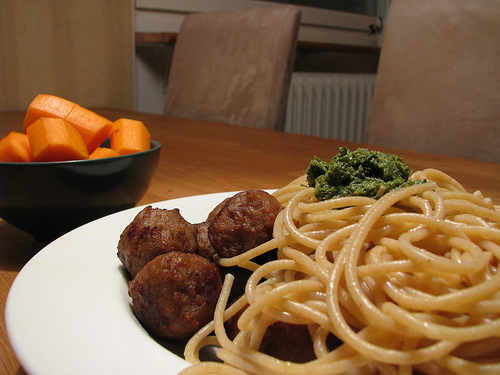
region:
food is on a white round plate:
[1, 146, 496, 371]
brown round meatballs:
[125, 248, 220, 335]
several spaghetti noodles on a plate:
[299, 201, 489, 363]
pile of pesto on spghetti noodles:
[306, 144, 411, 196]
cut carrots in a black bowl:
[1, 93, 160, 242]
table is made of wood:
[6, 102, 499, 198]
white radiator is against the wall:
[290, 70, 372, 132]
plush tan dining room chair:
[164, 6, 302, 128]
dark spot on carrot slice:
[111, 124, 120, 136]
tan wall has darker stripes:
[4, 7, 134, 91]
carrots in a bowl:
[0, 99, 180, 239]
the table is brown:
[143, 100, 227, 205]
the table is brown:
[151, 78, 273, 203]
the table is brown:
[201, 75, 303, 203]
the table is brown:
[100, 75, 262, 248]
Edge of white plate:
[20, 237, 74, 257]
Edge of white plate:
[10, 254, 27, 316]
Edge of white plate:
[2, 304, 28, 374]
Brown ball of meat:
[210, 191, 282, 271]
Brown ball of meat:
[111, 188, 187, 265]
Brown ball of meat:
[134, 261, 268, 352]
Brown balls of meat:
[117, 159, 287, 363]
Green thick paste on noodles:
[291, 140, 426, 225]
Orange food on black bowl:
[6, 81, 175, 195]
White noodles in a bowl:
[295, 201, 463, 371]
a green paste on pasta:
[298, 139, 420, 207]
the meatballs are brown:
[113, 189, 290, 360]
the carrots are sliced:
[12, 80, 123, 170]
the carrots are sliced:
[18, 98, 181, 200]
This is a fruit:
[11, 72, 159, 213]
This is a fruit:
[117, 96, 161, 193]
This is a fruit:
[17, 73, 82, 134]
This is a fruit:
[34, 113, 92, 183]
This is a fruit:
[57, 68, 112, 152]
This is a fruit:
[0, 111, 31, 185]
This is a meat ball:
[124, 251, 244, 359]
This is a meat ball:
[188, 173, 292, 255]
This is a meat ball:
[102, 179, 202, 264]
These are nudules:
[285, 159, 483, 370]